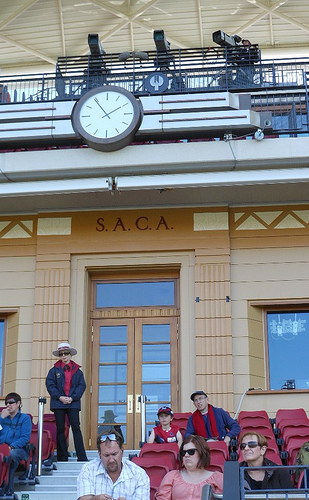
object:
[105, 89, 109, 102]
black line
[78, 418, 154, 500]
man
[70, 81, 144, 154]
clock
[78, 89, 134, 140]
face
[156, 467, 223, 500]
shirt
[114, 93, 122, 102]
number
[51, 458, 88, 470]
stairs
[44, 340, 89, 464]
woman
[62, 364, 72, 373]
tie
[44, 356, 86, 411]
jacket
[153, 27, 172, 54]
cameras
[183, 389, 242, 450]
man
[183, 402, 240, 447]
blue jacket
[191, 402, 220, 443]
red scarf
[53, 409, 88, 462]
black pants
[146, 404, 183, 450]
child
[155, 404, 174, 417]
hat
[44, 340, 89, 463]
man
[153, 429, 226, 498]
woman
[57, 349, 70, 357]
sunglasses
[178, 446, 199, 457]
sunglasses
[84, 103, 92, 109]
line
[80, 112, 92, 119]
number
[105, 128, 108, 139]
line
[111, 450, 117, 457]
eye